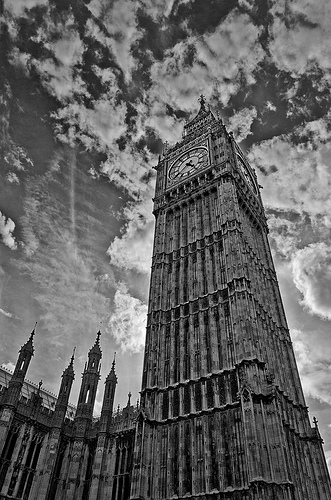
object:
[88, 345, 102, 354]
spire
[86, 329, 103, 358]
cap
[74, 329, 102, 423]
tower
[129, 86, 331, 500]
tower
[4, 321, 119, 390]
tops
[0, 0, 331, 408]
cloudy sky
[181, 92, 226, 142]
steeple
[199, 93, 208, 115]
spire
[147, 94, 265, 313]
gothic tower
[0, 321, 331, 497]
building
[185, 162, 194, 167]
hour handle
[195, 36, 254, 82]
cloud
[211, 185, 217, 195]
arch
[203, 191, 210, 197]
arch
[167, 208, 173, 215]
arch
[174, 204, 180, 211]
arch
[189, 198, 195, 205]
arch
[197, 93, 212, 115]
spire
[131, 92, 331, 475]
clock tower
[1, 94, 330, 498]
building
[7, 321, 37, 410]
spire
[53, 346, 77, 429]
spire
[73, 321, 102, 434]
spire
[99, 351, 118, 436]
spire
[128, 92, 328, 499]
building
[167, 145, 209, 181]
clock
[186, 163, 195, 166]
hour hand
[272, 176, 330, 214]
clouds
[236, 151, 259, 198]
clock face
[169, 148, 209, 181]
numerals